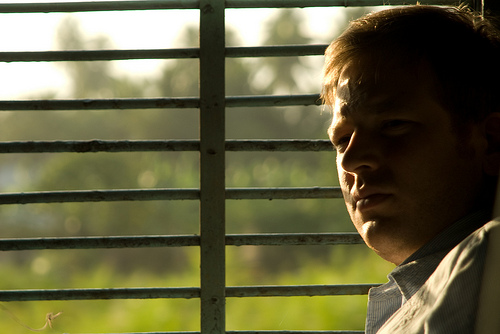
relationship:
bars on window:
[0, 92, 323, 111] [3, 5, 351, 332]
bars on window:
[0, 85, 323, 115] [3, 5, 351, 332]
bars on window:
[0, 135, 347, 157] [3, 5, 351, 332]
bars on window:
[2, 178, 351, 206] [3, 5, 351, 332]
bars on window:
[0, 227, 370, 247] [3, 5, 351, 332]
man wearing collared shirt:
[314, 1, 499, 333] [364, 219, 498, 332]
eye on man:
[368, 114, 415, 146] [314, 1, 499, 333]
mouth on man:
[344, 184, 381, 206] [314, 1, 499, 333]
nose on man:
[341, 130, 379, 174] [314, 1, 499, 333]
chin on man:
[357, 217, 419, 252] [314, 1, 499, 333]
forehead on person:
[327, 47, 422, 116] [311, 4, 493, 331]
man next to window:
[314, 23, 495, 311] [15, 27, 465, 321]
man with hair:
[314, 1, 499, 333] [324, 5, 497, 105]